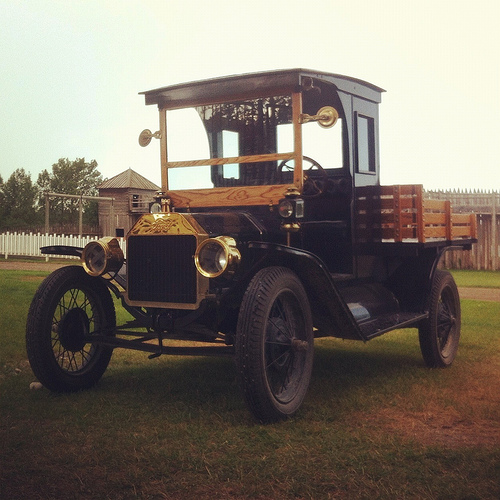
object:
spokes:
[264, 294, 311, 396]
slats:
[422, 212, 470, 224]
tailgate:
[377, 183, 419, 241]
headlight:
[194, 236, 241, 281]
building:
[95, 169, 162, 239]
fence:
[52, 233, 80, 246]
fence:
[454, 186, 499, 273]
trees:
[35, 156, 108, 227]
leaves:
[56, 155, 98, 193]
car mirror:
[298, 114, 310, 124]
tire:
[419, 270, 462, 367]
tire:
[236, 261, 319, 422]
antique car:
[23, 66, 480, 421]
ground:
[1, 255, 499, 495]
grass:
[3, 257, 498, 499]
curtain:
[194, 96, 293, 177]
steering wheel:
[276, 156, 326, 200]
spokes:
[52, 290, 100, 371]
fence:
[0, 230, 51, 262]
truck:
[24, 43, 471, 428]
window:
[165, 93, 297, 185]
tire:
[25, 265, 116, 394]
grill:
[125, 233, 197, 306]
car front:
[80, 194, 297, 321]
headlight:
[80, 236, 123, 277]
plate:
[56, 304, 90, 354]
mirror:
[138, 129, 163, 148]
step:
[304, 245, 426, 344]